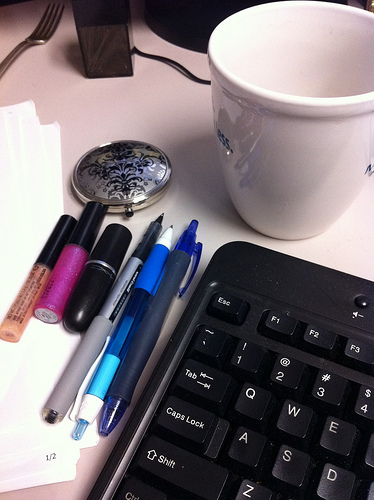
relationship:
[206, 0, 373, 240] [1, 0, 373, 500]
cup on desktop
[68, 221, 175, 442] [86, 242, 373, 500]
pens next to keyboard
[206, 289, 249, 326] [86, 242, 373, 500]
esc button on keyboard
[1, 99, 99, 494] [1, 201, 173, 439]
papers under items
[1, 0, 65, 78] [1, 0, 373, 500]
fork on desktop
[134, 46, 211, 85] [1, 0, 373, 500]
cord on desktop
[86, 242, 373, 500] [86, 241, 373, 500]
keyboard in corner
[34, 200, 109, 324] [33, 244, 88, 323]
container of lip gloss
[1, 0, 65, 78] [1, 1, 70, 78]
fork in corner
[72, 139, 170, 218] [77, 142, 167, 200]
pocket watch has a design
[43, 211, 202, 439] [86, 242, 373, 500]
pens next to keyboard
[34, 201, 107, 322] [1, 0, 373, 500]
lip gloss on desktop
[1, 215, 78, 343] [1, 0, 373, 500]
lip gloss on desktop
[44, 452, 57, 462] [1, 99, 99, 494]
numbers on papers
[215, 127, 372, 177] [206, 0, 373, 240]
blue on cup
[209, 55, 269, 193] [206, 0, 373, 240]
reflection on cup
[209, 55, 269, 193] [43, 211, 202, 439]
reflection of pens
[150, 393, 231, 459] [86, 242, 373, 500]
caps lock button on keyboard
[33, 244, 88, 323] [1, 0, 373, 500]
lip gloss on desktop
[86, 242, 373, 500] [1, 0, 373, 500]
keyboard on desktop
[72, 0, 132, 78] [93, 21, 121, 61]
box of paper clips